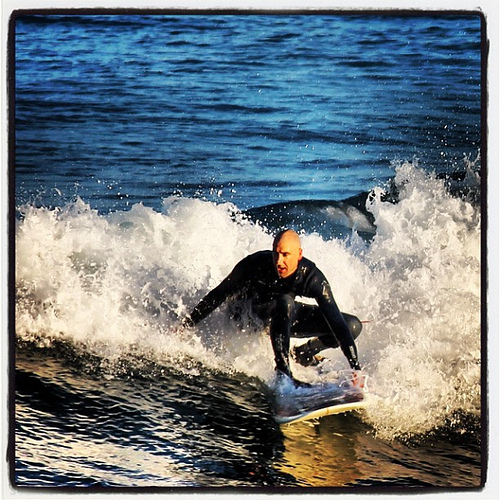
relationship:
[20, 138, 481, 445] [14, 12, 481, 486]
wave in water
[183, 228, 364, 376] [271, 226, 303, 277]
man has a head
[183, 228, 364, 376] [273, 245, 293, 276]
man has a face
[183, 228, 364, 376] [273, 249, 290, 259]
man has eyes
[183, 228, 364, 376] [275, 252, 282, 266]
man has a nose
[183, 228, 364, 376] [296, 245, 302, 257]
man has a ear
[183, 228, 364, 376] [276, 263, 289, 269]
man has a mouth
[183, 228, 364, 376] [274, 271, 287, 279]
man has a chin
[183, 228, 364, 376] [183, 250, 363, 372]
man wearing a wet suit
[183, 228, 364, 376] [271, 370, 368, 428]
man riding a surfboard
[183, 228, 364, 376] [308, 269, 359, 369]
man has a arm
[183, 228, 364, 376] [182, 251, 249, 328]
man has a arm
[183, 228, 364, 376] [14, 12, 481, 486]
man in water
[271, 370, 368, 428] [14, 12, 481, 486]
surfboard in water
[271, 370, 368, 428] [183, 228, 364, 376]
surfboard under man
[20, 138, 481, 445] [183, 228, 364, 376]
wave around man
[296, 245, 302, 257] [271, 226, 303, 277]
ear on head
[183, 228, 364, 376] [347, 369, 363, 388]
man has a hand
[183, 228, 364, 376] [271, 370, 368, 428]
man holding surfboard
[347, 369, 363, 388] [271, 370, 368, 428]
hand on surfboard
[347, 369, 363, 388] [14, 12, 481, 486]
hand in water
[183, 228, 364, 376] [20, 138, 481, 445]
man in wave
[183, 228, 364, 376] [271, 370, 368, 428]
man on surfboard